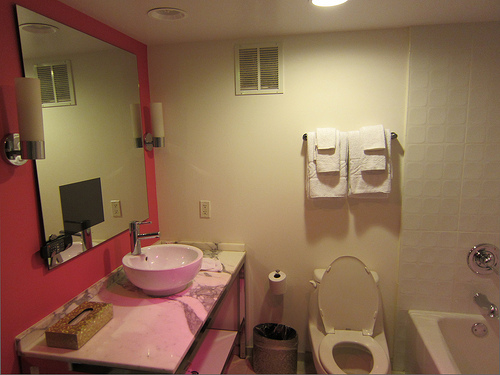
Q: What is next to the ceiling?
A: A heat vent.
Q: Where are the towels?
A: Towel rack on wall.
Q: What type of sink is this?
A: A bowl sink.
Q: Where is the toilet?
A: Next to the tub.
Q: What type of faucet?
A: A single lever faucet.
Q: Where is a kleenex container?
A: On left side of vanity.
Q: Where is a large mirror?
A: Hanging over sink vanity.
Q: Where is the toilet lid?
A: Lid is up.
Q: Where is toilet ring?
A: Ring is down.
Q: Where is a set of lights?
A: On sides of mirror.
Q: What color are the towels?
A: White.